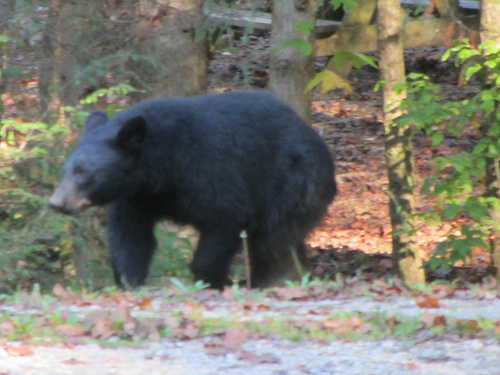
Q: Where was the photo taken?
A: It was taken at the forest.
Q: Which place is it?
A: It is a forest.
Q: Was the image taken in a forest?
A: Yes, it was taken in a forest.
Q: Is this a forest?
A: Yes, it is a forest.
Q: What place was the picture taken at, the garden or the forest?
A: It was taken at the forest.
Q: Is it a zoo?
A: No, it is a forest.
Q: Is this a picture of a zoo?
A: No, the picture is showing a forest.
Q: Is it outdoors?
A: Yes, it is outdoors.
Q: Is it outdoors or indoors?
A: It is outdoors.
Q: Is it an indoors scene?
A: No, it is outdoors.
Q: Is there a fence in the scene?
A: No, there are no fences.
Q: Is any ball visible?
A: No, there are no balls.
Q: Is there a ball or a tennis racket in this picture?
A: No, there are no balls or rackets.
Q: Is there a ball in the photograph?
A: No, there are no balls.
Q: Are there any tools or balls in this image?
A: No, there are no balls or tools.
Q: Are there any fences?
A: No, there are no fences.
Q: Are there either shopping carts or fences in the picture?
A: No, there are no fences or shopping carts.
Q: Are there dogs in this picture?
A: No, there are no dogs.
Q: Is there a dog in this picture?
A: No, there are no dogs.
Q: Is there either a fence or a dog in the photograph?
A: No, there are no dogs or fences.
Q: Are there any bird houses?
A: No, there are no bird houses.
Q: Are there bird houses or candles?
A: No, there are no bird houses or candles.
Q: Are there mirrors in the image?
A: No, there are no mirrors.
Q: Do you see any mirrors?
A: No, there are no mirrors.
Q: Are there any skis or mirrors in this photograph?
A: No, there are no mirrors or skis.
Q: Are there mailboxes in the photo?
A: No, there are no mailboxes.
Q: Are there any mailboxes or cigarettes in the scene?
A: No, there are no mailboxes or cigarettes.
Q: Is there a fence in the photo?
A: No, there are no fences.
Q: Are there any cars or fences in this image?
A: No, there are no fences or cars.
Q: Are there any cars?
A: No, there are no cars.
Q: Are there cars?
A: No, there are no cars.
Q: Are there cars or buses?
A: No, there are no cars or buses.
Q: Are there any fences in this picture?
A: No, there are no fences.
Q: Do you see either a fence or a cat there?
A: No, there are no fences or cats.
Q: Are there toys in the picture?
A: No, there are no toys.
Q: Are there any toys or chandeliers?
A: No, there are no toys or chandeliers.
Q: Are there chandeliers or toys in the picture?
A: No, there are no toys or chandeliers.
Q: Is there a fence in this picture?
A: No, there are no fences.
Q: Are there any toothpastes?
A: No, there are no toothpastes.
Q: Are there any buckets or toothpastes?
A: No, there are no toothpastes or buckets.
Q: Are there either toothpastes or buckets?
A: No, there are no toothpastes or buckets.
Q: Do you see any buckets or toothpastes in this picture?
A: No, there are no toothpastes or buckets.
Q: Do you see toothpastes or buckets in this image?
A: No, there are no toothpastes or buckets.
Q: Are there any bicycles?
A: No, there are no bicycles.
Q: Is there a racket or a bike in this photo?
A: No, there are no bikes or rackets.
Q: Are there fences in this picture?
A: No, there are no fences.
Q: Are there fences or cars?
A: No, there are no fences or cars.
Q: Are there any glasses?
A: No, there are no glasses.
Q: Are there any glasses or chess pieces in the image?
A: No, there are no glasses or chess pieces.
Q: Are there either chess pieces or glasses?
A: No, there are no glasses or chess pieces.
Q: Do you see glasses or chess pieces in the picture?
A: No, there are no glasses or chess pieces.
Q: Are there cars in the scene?
A: No, there are no cars.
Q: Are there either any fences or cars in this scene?
A: No, there are no cars or fences.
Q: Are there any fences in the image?
A: No, there are no fences.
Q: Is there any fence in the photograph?
A: No, there are no fences.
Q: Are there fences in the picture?
A: No, there are no fences.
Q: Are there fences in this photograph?
A: No, there are no fences.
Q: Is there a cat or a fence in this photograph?
A: No, there are no fences or cats.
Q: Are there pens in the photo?
A: No, there are no pens.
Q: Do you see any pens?
A: No, there are no pens.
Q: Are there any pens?
A: No, there are no pens.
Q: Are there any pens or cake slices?
A: No, there are no pens or cake slices.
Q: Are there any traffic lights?
A: No, there are no traffic lights.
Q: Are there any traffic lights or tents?
A: No, there are no traffic lights or tents.